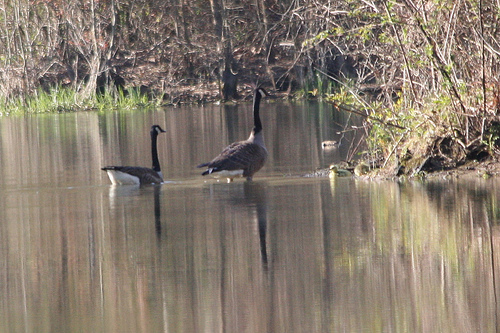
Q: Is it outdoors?
A: Yes, it is outdoors.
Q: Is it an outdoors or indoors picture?
A: It is outdoors.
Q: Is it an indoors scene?
A: No, it is outdoors.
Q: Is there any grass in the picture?
A: Yes, there is grass.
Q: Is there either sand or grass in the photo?
A: Yes, there is grass.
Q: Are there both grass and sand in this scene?
A: No, there is grass but no sand.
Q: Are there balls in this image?
A: No, there are no balls.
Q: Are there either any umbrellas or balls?
A: No, there are no balls or umbrellas.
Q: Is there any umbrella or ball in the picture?
A: No, there are no balls or umbrellas.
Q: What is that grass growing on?
A: The grass is growing on the shore.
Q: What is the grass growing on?
A: The grass is growing on the shore.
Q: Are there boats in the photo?
A: No, there are no boats.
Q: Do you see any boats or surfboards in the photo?
A: No, there are no boats or surfboards.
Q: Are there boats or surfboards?
A: No, there are no boats or surfboards.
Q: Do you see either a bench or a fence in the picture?
A: No, there are no fences or benches.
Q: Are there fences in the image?
A: No, there are no fences.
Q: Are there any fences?
A: No, there are no fences.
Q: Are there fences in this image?
A: No, there are no fences.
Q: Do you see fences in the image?
A: No, there are no fences.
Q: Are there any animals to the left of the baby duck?
A: Yes, there is an animal to the left of the duck.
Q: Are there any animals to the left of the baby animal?
A: Yes, there is an animal to the left of the duck.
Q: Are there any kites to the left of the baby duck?
A: No, there is an animal to the left of the duck.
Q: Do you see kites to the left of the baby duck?
A: No, there is an animal to the left of the duck.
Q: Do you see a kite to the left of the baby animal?
A: No, there is an animal to the left of the duck.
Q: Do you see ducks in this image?
A: Yes, there is a duck.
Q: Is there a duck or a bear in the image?
A: Yes, there is a duck.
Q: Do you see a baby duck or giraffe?
A: Yes, there is a baby duck.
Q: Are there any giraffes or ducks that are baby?
A: Yes, the duck is a baby.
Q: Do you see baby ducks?
A: Yes, there is a baby duck.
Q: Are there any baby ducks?
A: Yes, there is a baby duck.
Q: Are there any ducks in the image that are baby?
A: Yes, there is a duck that is a baby.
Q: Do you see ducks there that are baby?
A: Yes, there is a duck that is a baby.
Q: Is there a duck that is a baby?
A: Yes, there is a duck that is a baby.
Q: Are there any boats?
A: No, there are no boats.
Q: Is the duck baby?
A: Yes, the duck is a baby.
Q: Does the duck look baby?
A: Yes, the duck is a baby.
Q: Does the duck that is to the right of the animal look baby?
A: Yes, the duck is a baby.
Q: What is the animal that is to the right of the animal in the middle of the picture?
A: The animal is a duck.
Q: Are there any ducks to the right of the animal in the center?
A: Yes, there is a duck to the right of the animal.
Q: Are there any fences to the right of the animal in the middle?
A: No, there is a duck to the right of the animal.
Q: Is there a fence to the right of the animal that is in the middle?
A: No, there is a duck to the right of the animal.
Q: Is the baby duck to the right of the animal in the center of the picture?
A: Yes, the duck is to the right of the animal.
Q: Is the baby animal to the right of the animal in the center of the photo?
A: Yes, the duck is to the right of the animal.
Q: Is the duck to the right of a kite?
A: No, the duck is to the right of the animal.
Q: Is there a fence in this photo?
A: No, there are no fences.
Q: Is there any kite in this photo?
A: No, there are no kites.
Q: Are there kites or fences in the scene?
A: No, there are no kites or fences.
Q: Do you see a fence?
A: No, there are no fences.